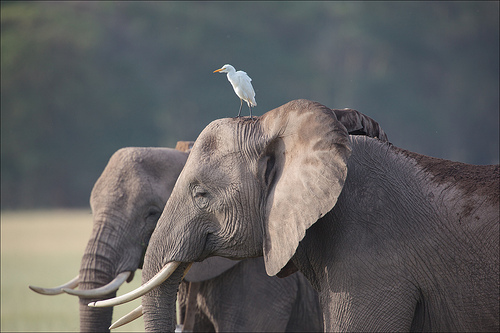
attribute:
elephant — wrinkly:
[88, 99, 499, 330]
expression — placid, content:
[134, 201, 161, 229]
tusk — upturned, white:
[26, 274, 82, 297]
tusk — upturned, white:
[67, 272, 132, 297]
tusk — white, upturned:
[88, 260, 180, 309]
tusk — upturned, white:
[106, 306, 144, 332]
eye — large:
[190, 184, 211, 203]